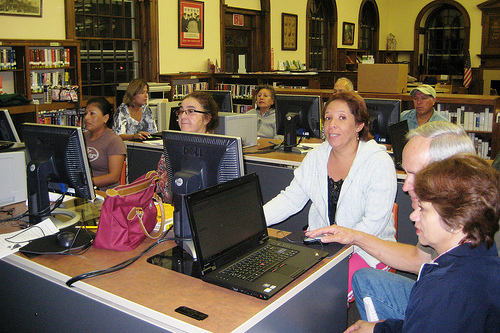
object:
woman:
[345, 157, 500, 332]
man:
[401, 83, 440, 129]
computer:
[363, 94, 401, 142]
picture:
[176, 1, 208, 52]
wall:
[1, 4, 398, 89]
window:
[68, 0, 160, 107]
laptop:
[179, 173, 326, 298]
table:
[127, 129, 430, 246]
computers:
[204, 84, 402, 147]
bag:
[96, 162, 166, 251]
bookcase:
[1, 42, 86, 132]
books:
[24, 44, 76, 125]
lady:
[251, 84, 280, 143]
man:
[400, 115, 475, 211]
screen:
[183, 173, 271, 265]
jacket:
[264, 140, 399, 241]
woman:
[257, 91, 396, 246]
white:
[354, 155, 397, 236]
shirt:
[83, 130, 128, 181]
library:
[5, 0, 491, 224]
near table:
[1, 190, 356, 332]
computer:
[158, 127, 245, 267]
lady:
[105, 86, 214, 195]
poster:
[283, 11, 297, 52]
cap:
[410, 78, 436, 99]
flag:
[459, 42, 474, 96]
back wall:
[391, 0, 499, 94]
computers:
[1, 106, 245, 245]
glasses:
[173, 104, 211, 122]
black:
[213, 212, 261, 255]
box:
[360, 58, 414, 98]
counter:
[258, 86, 495, 100]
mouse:
[293, 227, 334, 254]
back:
[19, 123, 93, 202]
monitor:
[18, 120, 96, 203]